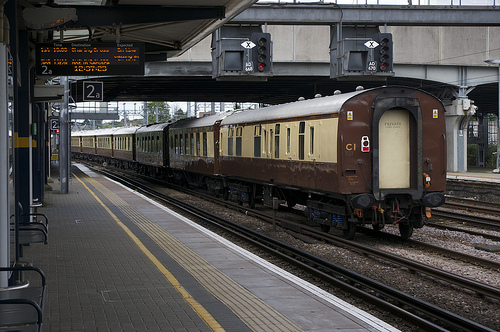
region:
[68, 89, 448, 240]
a brown and yellow passenger train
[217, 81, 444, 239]
the last car on a train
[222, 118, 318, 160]
a row of windows on a railroad car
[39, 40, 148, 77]
an overhead lighted sign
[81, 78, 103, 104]
a black sign with a white letter and number on it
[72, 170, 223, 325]
a yellow line painted on a platform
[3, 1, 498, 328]
a train station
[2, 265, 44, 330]
a black metal bench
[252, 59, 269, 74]
a bright red light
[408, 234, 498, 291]
a portion of the train track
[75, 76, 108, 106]
Platform identification number on ceiling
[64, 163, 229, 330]
Yellow platform warning line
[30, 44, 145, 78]
Illuminated train information sign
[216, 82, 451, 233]
Last car on passenger train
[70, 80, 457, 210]
Passenger train leaving station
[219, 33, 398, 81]
Train traffic signal lights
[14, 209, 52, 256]
Metal bench on train platform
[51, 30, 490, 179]
Overpass crossing train tracks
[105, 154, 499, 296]
Metal rails for trains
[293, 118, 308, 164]
Window on train car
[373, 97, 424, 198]
rear door on train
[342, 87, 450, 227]
brown and white rear end of train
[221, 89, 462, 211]
brown and white train car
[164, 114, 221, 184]
brown and white train car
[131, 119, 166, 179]
brown and white train car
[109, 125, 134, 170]
brown and white train car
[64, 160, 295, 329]
yellow painted lines on platform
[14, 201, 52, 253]
metal bench on platform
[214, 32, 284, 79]
train traffic signal above trains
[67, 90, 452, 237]
brown and white train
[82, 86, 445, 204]
Tan and brown train.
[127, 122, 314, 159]
Windows on side of train.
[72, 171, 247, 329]
Yellow lines on train platform.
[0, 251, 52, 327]
Bench on train platform.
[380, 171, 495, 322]
Railroad tracks at train station.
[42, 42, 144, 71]
Sign hanging over platform.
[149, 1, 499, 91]
Bridge over railroad tracks.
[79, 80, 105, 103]
Black and white sign.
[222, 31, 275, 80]
Traffic sign over train.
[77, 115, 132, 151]
Sun shining on train.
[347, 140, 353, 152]
The letter C on the train.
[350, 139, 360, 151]
The letter I on the train.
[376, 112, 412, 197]
The door of the train.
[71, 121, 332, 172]
The side windows of the train.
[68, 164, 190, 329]
The yellow line on the platform.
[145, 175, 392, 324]
The white line on teh platform.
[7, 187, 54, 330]
The chairs on the left.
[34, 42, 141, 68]
The marquee information display.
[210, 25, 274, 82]
The traffic light box on the left.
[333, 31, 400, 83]
The traffic light box on the right.